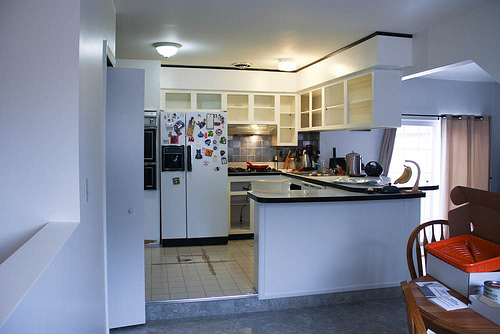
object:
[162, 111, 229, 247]
freezer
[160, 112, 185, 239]
white door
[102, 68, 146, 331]
door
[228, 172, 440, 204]
counter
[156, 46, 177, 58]
bulb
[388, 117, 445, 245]
glass door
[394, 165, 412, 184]
bananas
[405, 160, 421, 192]
holder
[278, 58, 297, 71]
light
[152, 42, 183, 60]
light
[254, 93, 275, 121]
door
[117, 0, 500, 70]
ceiling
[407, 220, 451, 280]
chair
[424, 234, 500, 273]
tray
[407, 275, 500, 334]
table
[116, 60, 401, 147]
shelves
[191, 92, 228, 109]
door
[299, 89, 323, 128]
glass door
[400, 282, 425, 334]
chair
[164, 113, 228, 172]
magnet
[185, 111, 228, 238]
fridge door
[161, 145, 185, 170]
dispenser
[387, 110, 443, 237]
window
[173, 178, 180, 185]
photo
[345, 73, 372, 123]
door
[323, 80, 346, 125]
door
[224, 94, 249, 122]
door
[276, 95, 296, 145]
door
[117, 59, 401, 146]
cabinet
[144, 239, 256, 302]
tile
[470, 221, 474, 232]
cutout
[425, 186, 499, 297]
box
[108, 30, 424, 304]
kitchen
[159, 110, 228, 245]
fridge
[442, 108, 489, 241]
curtain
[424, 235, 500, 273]
pan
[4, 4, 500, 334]
photo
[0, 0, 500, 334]
room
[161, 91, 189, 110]
door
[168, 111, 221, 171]
glare